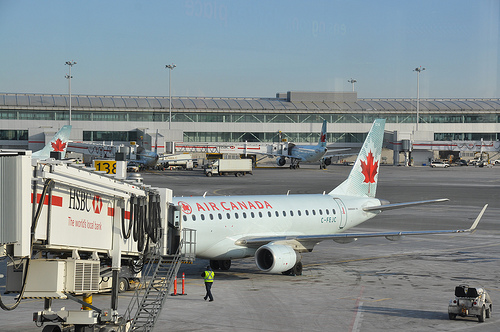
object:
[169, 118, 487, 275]
plane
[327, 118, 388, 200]
tail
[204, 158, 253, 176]
truck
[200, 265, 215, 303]
man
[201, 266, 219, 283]
vest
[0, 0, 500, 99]
sky